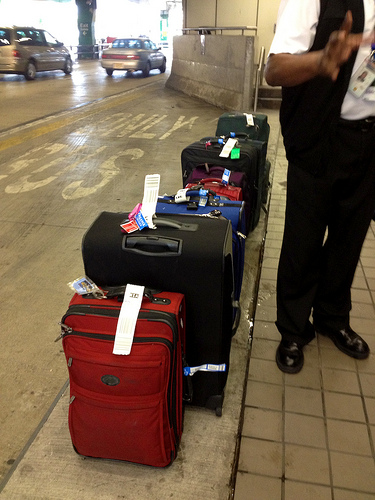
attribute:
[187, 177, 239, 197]
luggage — red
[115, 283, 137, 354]
tag — white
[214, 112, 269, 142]
bag — dark green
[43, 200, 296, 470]
luggage — red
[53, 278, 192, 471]
luggage — red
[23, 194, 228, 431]
bag — red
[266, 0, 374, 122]
shirt — white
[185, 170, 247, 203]
luggage — red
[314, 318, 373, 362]
shoe — black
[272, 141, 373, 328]
pants — black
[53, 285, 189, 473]
suitcase — red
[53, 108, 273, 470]
luggage — red